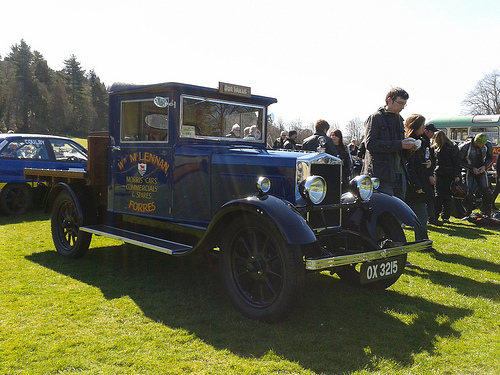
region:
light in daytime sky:
[0, 2, 497, 125]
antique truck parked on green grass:
[0, 79, 497, 372]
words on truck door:
[113, 93, 172, 220]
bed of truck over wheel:
[25, 139, 110, 257]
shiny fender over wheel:
[215, 195, 314, 323]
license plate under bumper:
[305, 240, 433, 282]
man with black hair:
[381, 85, 408, 102]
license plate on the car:
[357, 251, 407, 281]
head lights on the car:
[302, 171, 389, 203]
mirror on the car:
[148, 88, 172, 114]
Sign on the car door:
[105, 141, 171, 221]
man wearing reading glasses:
[390, 95, 410, 110]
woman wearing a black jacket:
[401, 135, 441, 199]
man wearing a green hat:
[468, 128, 489, 148]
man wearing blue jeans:
[373, 168, 414, 205]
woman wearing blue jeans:
[413, 201, 435, 243]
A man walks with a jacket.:
[363, 85, 405, 200]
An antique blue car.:
[47, 80, 432, 321]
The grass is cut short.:
[2, 135, 497, 372]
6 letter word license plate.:
[360, 252, 405, 278]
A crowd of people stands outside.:
[272, 85, 493, 226]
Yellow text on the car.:
[115, 150, 167, 211]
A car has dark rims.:
[216, 210, 301, 316]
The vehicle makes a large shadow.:
[22, 231, 477, 371]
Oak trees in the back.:
[0, 37, 108, 137]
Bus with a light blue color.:
[428, 114, 498, 193]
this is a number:
[362, 265, 377, 285]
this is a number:
[371, 264, 380, 281]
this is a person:
[357, 76, 418, 238]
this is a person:
[396, 100, 438, 245]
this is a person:
[425, 120, 463, 227]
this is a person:
[460, 122, 495, 213]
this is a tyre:
[41, 185, 87, 260]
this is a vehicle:
[0, 99, 100, 219]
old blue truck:
[62, 78, 399, 323]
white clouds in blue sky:
[63, 27, 83, 44]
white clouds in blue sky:
[91, 18, 128, 65]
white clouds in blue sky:
[125, 19, 156, 60]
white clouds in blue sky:
[174, 12, 218, 53]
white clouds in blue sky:
[287, 66, 315, 100]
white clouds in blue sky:
[325, 52, 339, 72]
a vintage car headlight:
[302, 174, 327, 206]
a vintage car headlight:
[350, 171, 374, 206]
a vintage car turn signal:
[254, 173, 270, 193]